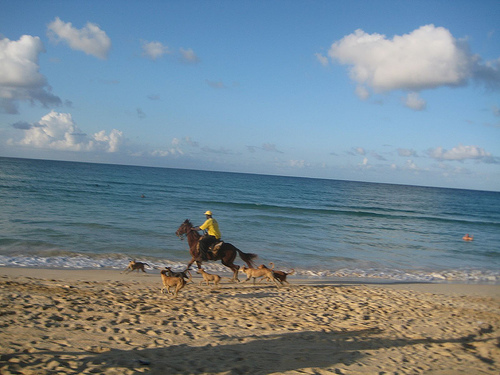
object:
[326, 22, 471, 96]
clouds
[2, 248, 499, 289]
tide water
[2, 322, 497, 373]
shadow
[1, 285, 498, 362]
ground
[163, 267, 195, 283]
dogs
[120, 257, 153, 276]
dogs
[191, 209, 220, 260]
man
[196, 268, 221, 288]
dog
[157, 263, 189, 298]
dog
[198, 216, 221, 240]
shirt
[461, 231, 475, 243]
man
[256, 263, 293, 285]
dogs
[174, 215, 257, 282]
horse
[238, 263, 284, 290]
dogs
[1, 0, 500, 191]
skies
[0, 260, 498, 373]
beach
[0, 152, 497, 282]
ocean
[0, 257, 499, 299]
shore